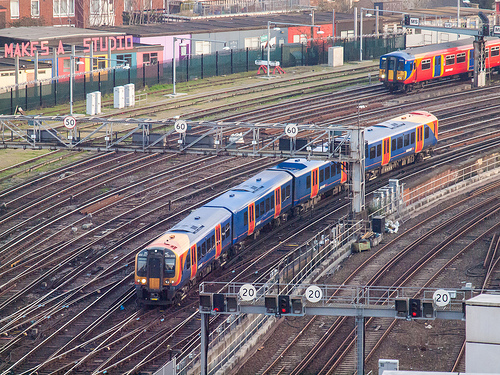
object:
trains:
[374, 31, 496, 89]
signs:
[236, 279, 453, 310]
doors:
[213, 222, 223, 257]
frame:
[0, 115, 370, 252]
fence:
[0, 34, 406, 133]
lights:
[197, 294, 435, 315]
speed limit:
[237, 282, 450, 309]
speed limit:
[58, 116, 79, 131]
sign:
[2, 32, 134, 63]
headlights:
[136, 277, 174, 285]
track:
[0, 76, 500, 374]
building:
[283, 21, 334, 59]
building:
[0, 28, 137, 95]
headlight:
[140, 278, 171, 284]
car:
[132, 109, 439, 309]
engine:
[131, 200, 236, 309]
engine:
[377, 37, 500, 83]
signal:
[58, 115, 299, 149]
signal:
[263, 290, 304, 320]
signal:
[393, 299, 441, 322]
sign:
[242, 287, 255, 298]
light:
[278, 294, 291, 313]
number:
[174, 122, 187, 132]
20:
[239, 284, 256, 300]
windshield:
[136, 255, 149, 276]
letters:
[4, 34, 135, 59]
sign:
[307, 288, 321, 301]